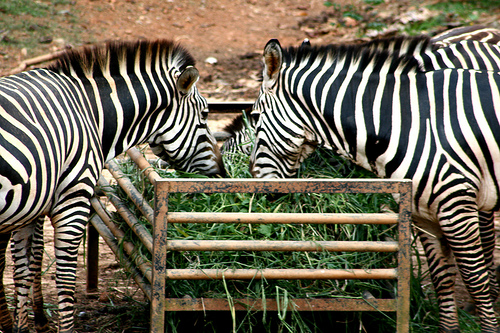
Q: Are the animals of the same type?
A: Yes, all the animals are zebras.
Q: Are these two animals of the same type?
A: Yes, all the animals are zebras.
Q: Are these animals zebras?
A: Yes, all the animals are zebras.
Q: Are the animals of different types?
A: No, all the animals are zebras.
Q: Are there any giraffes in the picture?
A: No, there are no giraffes.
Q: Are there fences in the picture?
A: Yes, there is a fence.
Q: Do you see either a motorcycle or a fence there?
A: Yes, there is a fence.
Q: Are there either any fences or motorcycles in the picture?
A: Yes, there is a fence.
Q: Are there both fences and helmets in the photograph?
A: No, there is a fence but no helmets.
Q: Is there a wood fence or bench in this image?
A: Yes, there is a wood fence.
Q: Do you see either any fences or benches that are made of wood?
A: Yes, the fence is made of wood.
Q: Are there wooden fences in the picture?
A: Yes, there is a wood fence.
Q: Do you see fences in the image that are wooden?
A: Yes, there is a fence that is wooden.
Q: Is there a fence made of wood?
A: Yes, there is a fence that is made of wood.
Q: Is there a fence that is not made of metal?
A: Yes, there is a fence that is made of wood.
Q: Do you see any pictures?
A: No, there are no pictures.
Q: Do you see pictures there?
A: No, there are no pictures.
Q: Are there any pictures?
A: No, there are no pictures.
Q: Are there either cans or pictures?
A: No, there are no pictures or cans.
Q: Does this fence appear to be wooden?
A: Yes, the fence is wooden.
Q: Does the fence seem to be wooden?
A: Yes, the fence is wooden.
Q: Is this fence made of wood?
A: Yes, the fence is made of wood.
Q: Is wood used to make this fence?
A: Yes, the fence is made of wood.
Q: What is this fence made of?
A: The fence is made of wood.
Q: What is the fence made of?
A: The fence is made of wood.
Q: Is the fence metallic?
A: No, the fence is wooden.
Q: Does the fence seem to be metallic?
A: No, the fence is wooden.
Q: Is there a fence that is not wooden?
A: No, there is a fence but it is wooden.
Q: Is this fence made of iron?
A: No, the fence is made of wood.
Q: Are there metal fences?
A: No, there is a fence but it is made of wood.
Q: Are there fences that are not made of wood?
A: No, there is a fence but it is made of wood.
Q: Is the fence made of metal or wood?
A: The fence is made of wood.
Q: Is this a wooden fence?
A: Yes, this is a wooden fence.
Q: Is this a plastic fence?
A: No, this is a wooden fence.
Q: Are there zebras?
A: Yes, there is a zebra.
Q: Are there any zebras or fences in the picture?
A: Yes, there is a zebra.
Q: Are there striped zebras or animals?
A: Yes, there is a striped zebra.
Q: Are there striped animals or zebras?
A: Yes, there is a striped zebra.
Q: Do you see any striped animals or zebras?
A: Yes, there is a striped zebra.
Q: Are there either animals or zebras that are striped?
A: Yes, the zebra is striped.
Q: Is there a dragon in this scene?
A: No, there are no dragons.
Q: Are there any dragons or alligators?
A: No, there are no dragons or alligators.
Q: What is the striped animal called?
A: The animal is a zebra.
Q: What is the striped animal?
A: The animal is a zebra.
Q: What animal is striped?
A: The animal is a zebra.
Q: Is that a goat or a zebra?
A: That is a zebra.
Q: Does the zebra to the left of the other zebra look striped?
A: Yes, the zebra is striped.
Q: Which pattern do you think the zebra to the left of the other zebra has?
A: The zebra has striped pattern.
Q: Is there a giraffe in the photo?
A: No, there are no giraffes.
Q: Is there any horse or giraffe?
A: No, there are no giraffes or horses.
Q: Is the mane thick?
A: Yes, the mane is thick.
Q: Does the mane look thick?
A: Yes, the mane is thick.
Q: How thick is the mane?
A: The mane is thick.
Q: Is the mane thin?
A: No, the mane is thick.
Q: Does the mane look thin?
A: No, the mane is thick.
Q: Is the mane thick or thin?
A: The mane is thick.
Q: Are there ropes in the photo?
A: No, there are no ropes.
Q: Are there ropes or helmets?
A: No, there are no ropes or helmets.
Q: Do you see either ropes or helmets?
A: No, there are no ropes or helmets.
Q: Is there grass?
A: Yes, there is grass.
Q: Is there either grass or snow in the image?
A: Yes, there is grass.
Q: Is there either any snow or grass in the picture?
A: Yes, there is grass.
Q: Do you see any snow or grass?
A: Yes, there is grass.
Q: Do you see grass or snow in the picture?
A: Yes, there is grass.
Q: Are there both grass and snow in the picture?
A: No, there is grass but no snow.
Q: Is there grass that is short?
A: Yes, there is short grass.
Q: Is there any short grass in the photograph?
A: Yes, there is short grass.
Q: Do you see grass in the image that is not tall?
A: Yes, there is short grass.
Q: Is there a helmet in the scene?
A: No, there are no helmets.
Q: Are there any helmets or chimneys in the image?
A: No, there are no helmets or chimneys.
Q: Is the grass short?
A: Yes, the grass is short.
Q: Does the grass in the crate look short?
A: Yes, the grass is short.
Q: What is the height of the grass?
A: The grass is short.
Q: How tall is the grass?
A: The grass is short.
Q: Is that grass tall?
A: No, the grass is short.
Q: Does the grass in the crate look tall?
A: No, the grass is short.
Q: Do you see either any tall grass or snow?
A: No, there is grass but it is short.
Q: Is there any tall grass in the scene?
A: No, there is grass but it is short.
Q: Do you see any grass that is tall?
A: No, there is grass but it is short.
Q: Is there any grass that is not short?
A: No, there is grass but it is short.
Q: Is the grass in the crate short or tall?
A: The grass is short.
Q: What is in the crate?
A: The grass is in the crate.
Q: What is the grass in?
A: The grass is in the crate.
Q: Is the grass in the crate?
A: Yes, the grass is in the crate.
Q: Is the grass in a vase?
A: No, the grass is in the crate.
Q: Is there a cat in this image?
A: No, there are no cats.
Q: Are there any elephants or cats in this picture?
A: No, there are no cats or elephants.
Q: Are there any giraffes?
A: No, there are no giraffes.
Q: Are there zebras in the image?
A: Yes, there is a zebra.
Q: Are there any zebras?
A: Yes, there is a zebra.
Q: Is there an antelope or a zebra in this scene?
A: Yes, there is a zebra.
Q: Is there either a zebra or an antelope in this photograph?
A: Yes, there is a zebra.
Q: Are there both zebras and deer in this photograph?
A: No, there is a zebra but no deer.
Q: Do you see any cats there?
A: No, there are no cats.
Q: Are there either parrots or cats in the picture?
A: No, there are no cats or parrots.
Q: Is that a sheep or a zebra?
A: That is a zebra.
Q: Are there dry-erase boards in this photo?
A: No, there are no dry-erase boards.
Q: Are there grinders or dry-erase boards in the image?
A: No, there are no dry-erase boards or grinders.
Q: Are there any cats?
A: No, there are no cats.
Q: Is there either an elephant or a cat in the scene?
A: No, there are no cats or elephants.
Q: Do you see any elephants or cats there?
A: No, there are no cats or elephants.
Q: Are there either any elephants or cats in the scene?
A: No, there are no cats or elephants.